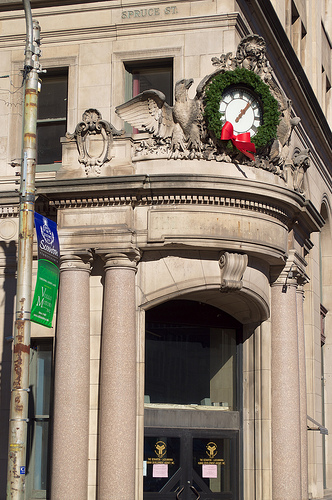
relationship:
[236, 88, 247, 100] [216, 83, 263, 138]
roman numeral on clock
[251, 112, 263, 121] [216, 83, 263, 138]
roman numeral on clock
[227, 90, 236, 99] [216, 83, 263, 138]
roman numeral on clock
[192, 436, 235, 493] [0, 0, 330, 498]
window on building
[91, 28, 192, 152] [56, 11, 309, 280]
window on building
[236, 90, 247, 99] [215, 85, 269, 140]
roman numeral on clock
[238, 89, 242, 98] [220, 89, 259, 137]
roman numeral on clock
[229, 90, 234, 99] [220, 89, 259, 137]
roman numeral on clock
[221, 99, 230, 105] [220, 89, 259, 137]
roman numeral on clock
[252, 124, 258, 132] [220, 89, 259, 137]
roman numeral on clock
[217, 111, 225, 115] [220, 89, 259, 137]
roman numeral on clock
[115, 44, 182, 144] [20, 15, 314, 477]
window on a building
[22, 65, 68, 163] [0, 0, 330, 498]
window on a building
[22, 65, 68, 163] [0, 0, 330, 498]
window on building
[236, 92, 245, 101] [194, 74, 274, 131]
number on clock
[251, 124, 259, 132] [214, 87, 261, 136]
number on clock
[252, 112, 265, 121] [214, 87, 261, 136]
number on clock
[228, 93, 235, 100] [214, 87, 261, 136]
number on clock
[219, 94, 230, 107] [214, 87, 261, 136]
number on clock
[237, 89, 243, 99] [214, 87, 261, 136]
number on clock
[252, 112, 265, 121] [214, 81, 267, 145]
number on clock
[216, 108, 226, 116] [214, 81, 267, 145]
number on clock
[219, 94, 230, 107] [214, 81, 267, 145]
number on clock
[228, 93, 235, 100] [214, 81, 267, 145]
number on clock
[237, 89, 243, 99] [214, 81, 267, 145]
number on clock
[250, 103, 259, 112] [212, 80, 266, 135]
number on clock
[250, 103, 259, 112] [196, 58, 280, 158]
number on clock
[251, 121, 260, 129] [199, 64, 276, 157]
numeral on clock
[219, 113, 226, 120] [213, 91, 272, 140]
numeral on clock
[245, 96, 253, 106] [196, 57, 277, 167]
roman numeral on clock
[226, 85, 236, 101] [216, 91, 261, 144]
roman numeral on clock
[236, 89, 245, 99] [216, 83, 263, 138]
roman numeral on clock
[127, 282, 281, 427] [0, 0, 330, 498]
window on building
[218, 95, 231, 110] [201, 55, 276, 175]
number on clock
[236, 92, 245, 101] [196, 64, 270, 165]
number on clock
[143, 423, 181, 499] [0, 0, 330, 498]
window on building